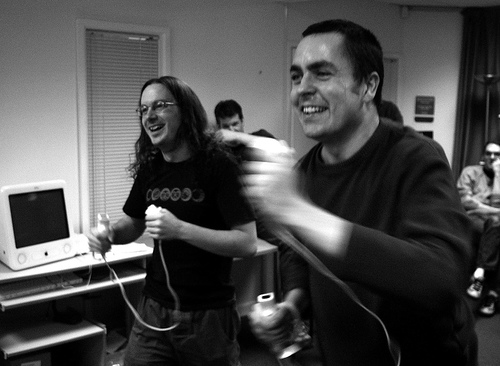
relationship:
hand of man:
[241, 146, 292, 217] [225, 11, 478, 361]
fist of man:
[142, 207, 171, 238] [94, 72, 269, 365]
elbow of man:
[403, 228, 464, 304] [225, 11, 478, 361]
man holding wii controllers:
[225, 11, 478, 361] [225, 116, 297, 360]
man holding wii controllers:
[94, 72, 269, 365] [93, 207, 164, 251]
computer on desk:
[4, 182, 73, 268] [1, 243, 177, 365]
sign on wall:
[412, 95, 435, 119] [403, 15, 468, 178]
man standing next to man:
[225, 11, 478, 361] [94, 72, 269, 365]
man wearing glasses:
[94, 72, 269, 365] [136, 98, 179, 115]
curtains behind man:
[450, 14, 499, 166] [463, 143, 498, 315]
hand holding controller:
[241, 146, 292, 217] [221, 130, 290, 172]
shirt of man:
[286, 116, 476, 355] [225, 11, 478, 361]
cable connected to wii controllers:
[266, 221, 402, 357] [225, 116, 297, 360]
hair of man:
[303, 16, 382, 78] [225, 11, 478, 361]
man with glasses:
[94, 72, 269, 365] [136, 98, 179, 115]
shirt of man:
[126, 151, 244, 298] [94, 72, 269, 365]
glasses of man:
[136, 98, 179, 115] [94, 72, 269, 365]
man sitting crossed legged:
[463, 143, 498, 315] [466, 221, 499, 300]